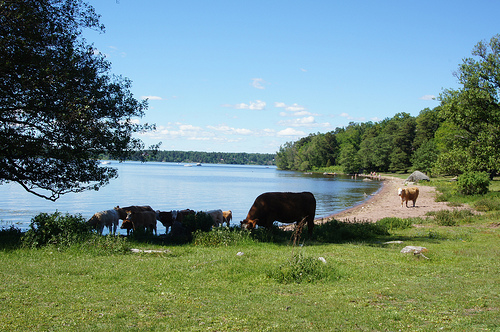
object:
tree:
[0, 0, 165, 203]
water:
[0, 159, 385, 237]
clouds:
[217, 100, 266, 112]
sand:
[270, 170, 487, 232]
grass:
[0, 165, 500, 332]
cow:
[397, 187, 419, 209]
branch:
[0, 173, 67, 202]